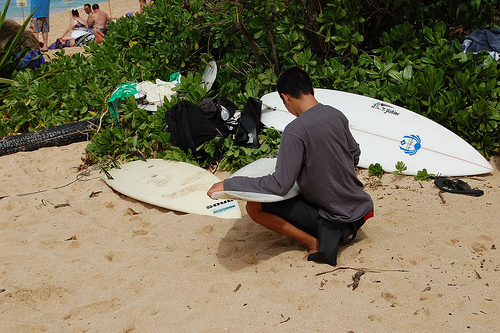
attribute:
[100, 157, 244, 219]
surfboard — white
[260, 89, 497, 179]
surfboard — white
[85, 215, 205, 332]
sand — tan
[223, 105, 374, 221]
shirt — grey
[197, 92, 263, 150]
wetsuit — black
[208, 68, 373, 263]
man — squatting, kneeling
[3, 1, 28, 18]
water — blue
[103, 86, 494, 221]
surfboards — white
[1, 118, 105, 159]
log — burnt